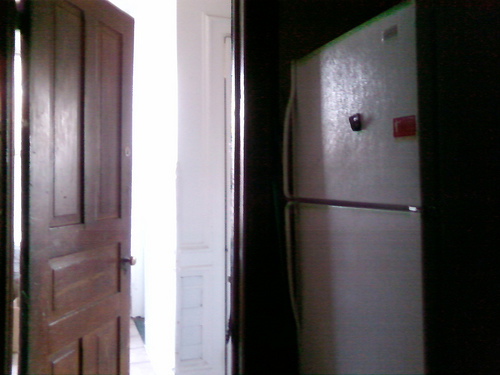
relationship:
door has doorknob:
[18, 1, 142, 372] [118, 250, 141, 272]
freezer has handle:
[273, 1, 499, 215] [274, 54, 311, 203]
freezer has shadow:
[283, 0, 499, 373] [276, 43, 353, 374]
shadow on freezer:
[276, 43, 353, 374] [283, 0, 499, 373]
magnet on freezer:
[341, 104, 370, 138] [283, 0, 499, 373]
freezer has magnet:
[283, 0, 499, 373] [341, 104, 370, 138]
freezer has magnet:
[283, 0, 499, 373] [389, 112, 420, 141]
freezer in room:
[283, 0, 499, 373] [229, 1, 499, 372]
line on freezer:
[286, 0, 419, 70] [283, 0, 499, 373]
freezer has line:
[283, 0, 499, 373] [286, 0, 419, 70]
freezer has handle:
[283, 0, 499, 373] [274, 54, 311, 203]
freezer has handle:
[283, 0, 499, 373] [276, 199, 309, 348]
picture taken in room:
[0, 1, 493, 372] [0, 0, 499, 374]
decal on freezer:
[378, 18, 405, 45] [283, 0, 499, 373]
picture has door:
[0, 1, 493, 372] [18, 1, 142, 372]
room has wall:
[0, 0, 499, 374] [110, 1, 177, 373]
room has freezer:
[229, 1, 499, 372] [283, 0, 499, 373]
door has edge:
[18, 1, 142, 372] [125, 12, 140, 374]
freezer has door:
[273, 1, 499, 215] [278, 1, 500, 212]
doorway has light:
[118, 3, 199, 374] [133, 2, 178, 374]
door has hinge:
[18, 1, 142, 372] [12, 4, 25, 35]